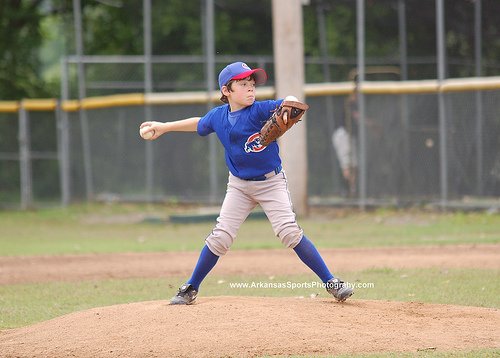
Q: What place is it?
A: It is a field.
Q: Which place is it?
A: It is a field.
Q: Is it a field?
A: Yes, it is a field.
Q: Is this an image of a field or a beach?
A: It is showing a field.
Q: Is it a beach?
A: No, it is a field.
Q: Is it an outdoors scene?
A: Yes, it is outdoors.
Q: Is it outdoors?
A: Yes, it is outdoors.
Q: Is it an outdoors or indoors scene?
A: It is outdoors.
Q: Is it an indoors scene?
A: No, it is outdoors.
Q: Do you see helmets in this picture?
A: No, there are no helmets.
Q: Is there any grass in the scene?
A: Yes, there is grass.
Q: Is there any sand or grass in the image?
A: Yes, there is grass.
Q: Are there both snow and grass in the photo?
A: No, there is grass but no snow.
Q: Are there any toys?
A: No, there are no toys.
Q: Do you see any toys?
A: No, there are no toys.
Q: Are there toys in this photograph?
A: No, there are no toys.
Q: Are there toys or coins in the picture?
A: No, there are no toys or coins.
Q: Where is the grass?
A: The grass is on the field.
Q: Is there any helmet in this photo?
A: No, there are no helmets.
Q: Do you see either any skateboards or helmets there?
A: No, there are no helmets or skateboards.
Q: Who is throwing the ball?
A: The boy is throwing the ball.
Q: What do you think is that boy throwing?
A: The boy is throwing the ball.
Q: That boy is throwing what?
A: The boy is throwing the ball.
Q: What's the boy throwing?
A: The boy is throwing the ball.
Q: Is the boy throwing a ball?
A: Yes, the boy is throwing a ball.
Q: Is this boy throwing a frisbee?
A: No, the boy is throwing a ball.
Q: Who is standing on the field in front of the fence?
A: The boy is standing on the field.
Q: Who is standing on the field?
A: The boy is standing on the field.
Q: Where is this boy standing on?
A: The boy is standing on the field.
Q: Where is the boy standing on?
A: The boy is standing on the field.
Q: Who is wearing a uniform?
A: The boy is wearing a uniform.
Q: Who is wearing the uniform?
A: The boy is wearing a uniform.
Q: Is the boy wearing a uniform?
A: Yes, the boy is wearing a uniform.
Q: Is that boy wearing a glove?
A: No, the boy is wearing a uniform.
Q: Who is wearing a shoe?
A: The boy is wearing a shoe.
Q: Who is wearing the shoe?
A: The boy is wearing a shoe.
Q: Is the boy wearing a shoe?
A: Yes, the boy is wearing a shoe.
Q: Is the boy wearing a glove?
A: No, the boy is wearing a shoe.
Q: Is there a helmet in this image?
A: No, there are no helmets.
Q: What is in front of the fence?
A: The field is in front of the fence.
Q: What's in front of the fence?
A: The field is in front of the fence.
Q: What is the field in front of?
A: The field is in front of the fence.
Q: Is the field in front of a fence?
A: Yes, the field is in front of a fence.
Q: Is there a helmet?
A: No, there are no helmets.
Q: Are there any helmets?
A: No, there are no helmets.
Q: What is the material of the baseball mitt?
A: The baseball mitt is made of leather.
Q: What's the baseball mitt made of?
A: The baseball mitt is made of leather.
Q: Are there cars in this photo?
A: No, there are no cars.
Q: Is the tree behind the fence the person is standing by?
A: Yes, the tree is behind the fence.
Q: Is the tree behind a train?
A: No, the tree is behind the fence.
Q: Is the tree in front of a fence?
A: No, the tree is behind a fence.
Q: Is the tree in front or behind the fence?
A: The tree is behind the fence.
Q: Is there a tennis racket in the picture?
A: No, there are no rackets.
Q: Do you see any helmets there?
A: No, there are no helmets.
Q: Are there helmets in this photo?
A: No, there are no helmets.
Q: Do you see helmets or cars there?
A: No, there are no helmets or cars.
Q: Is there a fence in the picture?
A: Yes, there is a fence.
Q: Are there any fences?
A: Yes, there is a fence.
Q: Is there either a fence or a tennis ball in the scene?
A: Yes, there is a fence.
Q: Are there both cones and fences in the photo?
A: No, there is a fence but no cones.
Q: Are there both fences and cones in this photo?
A: No, there is a fence but no cones.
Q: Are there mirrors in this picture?
A: No, there are no mirrors.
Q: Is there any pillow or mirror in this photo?
A: No, there are no mirrors or pillows.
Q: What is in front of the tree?
A: The fence is in front of the tree.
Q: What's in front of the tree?
A: The fence is in front of the tree.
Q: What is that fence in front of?
A: The fence is in front of the tree.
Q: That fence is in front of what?
A: The fence is in front of the tree.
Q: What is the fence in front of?
A: The fence is in front of the tree.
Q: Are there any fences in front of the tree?
A: Yes, there is a fence in front of the tree.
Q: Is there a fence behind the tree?
A: No, the fence is in front of the tree.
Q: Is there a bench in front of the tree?
A: No, there is a fence in front of the tree.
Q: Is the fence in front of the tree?
A: Yes, the fence is in front of the tree.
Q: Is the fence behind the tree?
A: No, the fence is in front of the tree.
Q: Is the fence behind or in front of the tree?
A: The fence is in front of the tree.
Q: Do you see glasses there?
A: No, there are no glasses.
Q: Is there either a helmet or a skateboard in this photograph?
A: No, there are no helmets or skateboards.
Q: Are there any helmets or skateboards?
A: No, there are no helmets or skateboards.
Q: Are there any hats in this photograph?
A: Yes, there is a hat.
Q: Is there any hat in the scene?
A: Yes, there is a hat.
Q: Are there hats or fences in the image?
A: Yes, there is a hat.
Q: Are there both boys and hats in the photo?
A: Yes, there are both a hat and a boy.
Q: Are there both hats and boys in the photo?
A: Yes, there are both a hat and a boy.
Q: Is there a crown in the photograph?
A: No, there are no crowns.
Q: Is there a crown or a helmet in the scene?
A: No, there are no crowns or helmets.